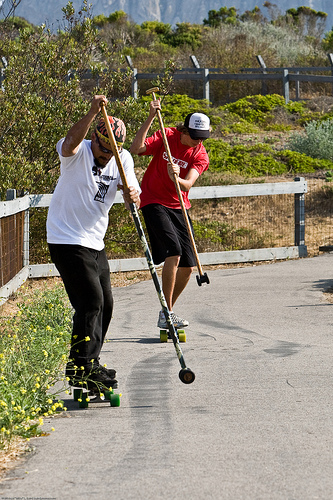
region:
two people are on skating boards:
[64, 74, 264, 365]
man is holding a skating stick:
[69, 90, 181, 418]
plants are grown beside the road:
[11, 288, 64, 397]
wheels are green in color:
[71, 365, 136, 422]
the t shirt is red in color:
[153, 127, 207, 198]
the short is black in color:
[151, 200, 214, 265]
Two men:
[19, 76, 239, 397]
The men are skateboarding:
[42, 75, 261, 415]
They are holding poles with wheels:
[97, 72, 242, 402]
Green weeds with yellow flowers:
[7, 289, 78, 442]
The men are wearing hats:
[87, 92, 218, 139]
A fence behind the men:
[4, 180, 325, 280]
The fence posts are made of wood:
[205, 173, 319, 261]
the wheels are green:
[70, 383, 121, 406]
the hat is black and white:
[182, 104, 213, 139]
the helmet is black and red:
[95, 111, 133, 145]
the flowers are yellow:
[29, 392, 71, 423]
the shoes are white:
[154, 304, 188, 325]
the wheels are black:
[193, 273, 212, 286]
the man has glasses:
[69, 111, 133, 402]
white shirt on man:
[42, 134, 139, 242]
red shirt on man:
[144, 121, 208, 205]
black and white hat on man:
[184, 111, 213, 142]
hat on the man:
[96, 110, 126, 145]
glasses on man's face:
[94, 134, 116, 153]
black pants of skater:
[48, 241, 109, 374]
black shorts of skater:
[141, 206, 196, 268]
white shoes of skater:
[157, 303, 185, 329]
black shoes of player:
[68, 360, 117, 386]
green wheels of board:
[68, 389, 120, 407]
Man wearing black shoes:
[61, 342, 122, 393]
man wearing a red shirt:
[146, 117, 192, 218]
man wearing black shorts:
[142, 201, 207, 274]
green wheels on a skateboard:
[73, 395, 119, 404]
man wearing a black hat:
[177, 105, 214, 139]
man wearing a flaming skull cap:
[91, 108, 128, 146]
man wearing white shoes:
[156, 305, 190, 330]